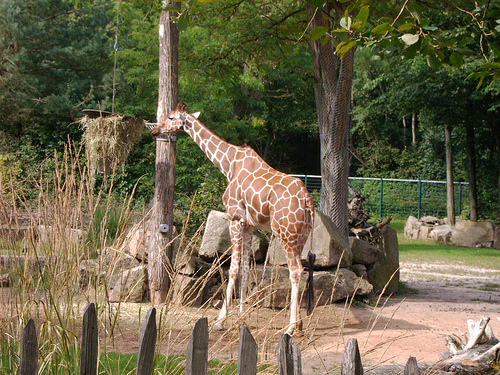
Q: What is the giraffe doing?
A: Eating.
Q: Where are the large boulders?
A: Front of giraffe.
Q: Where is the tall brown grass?
A: Bottom left.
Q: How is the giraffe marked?
A: Spots.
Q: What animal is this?
A: Giraffe.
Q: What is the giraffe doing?
A: Eating.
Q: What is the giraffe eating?
A: Hay.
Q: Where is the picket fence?
A: Foreground.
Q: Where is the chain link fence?
A: Background.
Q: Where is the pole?
A: Behind giraffe.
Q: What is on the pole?
A: Feeder for giraffe.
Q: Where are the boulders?
A: Around tree.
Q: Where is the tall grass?
A: Behind fence.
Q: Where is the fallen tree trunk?
A: Right of fence.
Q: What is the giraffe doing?
A: Eating.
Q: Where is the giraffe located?
A: Zoo.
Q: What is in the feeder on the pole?
A: Hay.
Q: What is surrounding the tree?
A: Fence.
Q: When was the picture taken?
A: During the day.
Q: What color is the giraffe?
A: Brown.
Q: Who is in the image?
A: There are no people in the image.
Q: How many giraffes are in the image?
A: One.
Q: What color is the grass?
A: Green.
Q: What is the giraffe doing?
A: Walking.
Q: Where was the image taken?
A: On a farm.